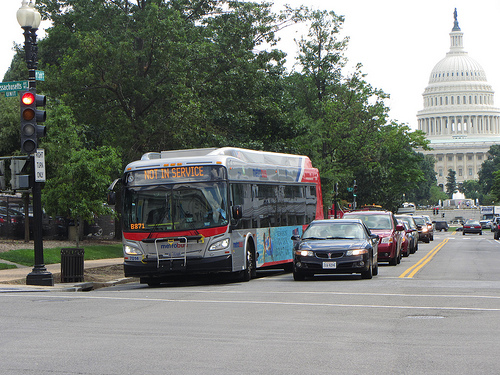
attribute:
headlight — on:
[294, 245, 367, 261]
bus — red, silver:
[114, 145, 326, 286]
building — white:
[415, 9, 498, 203]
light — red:
[18, 92, 38, 108]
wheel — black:
[240, 240, 260, 281]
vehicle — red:
[344, 206, 403, 266]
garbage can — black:
[56, 243, 87, 283]